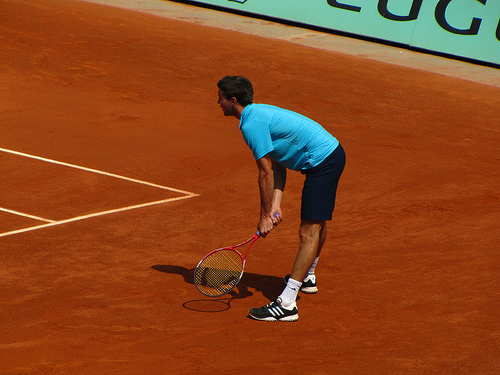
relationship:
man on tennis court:
[185, 77, 370, 350] [21, 29, 171, 332]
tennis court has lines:
[21, 29, 171, 332] [80, 208, 105, 231]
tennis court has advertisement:
[21, 29, 171, 332] [395, 6, 484, 62]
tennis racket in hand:
[182, 229, 268, 304] [251, 209, 280, 235]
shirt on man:
[243, 98, 323, 172] [185, 77, 370, 350]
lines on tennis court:
[80, 208, 105, 231] [21, 29, 171, 332]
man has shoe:
[185, 77, 370, 350] [247, 294, 290, 327]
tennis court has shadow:
[21, 29, 171, 332] [141, 258, 183, 281]